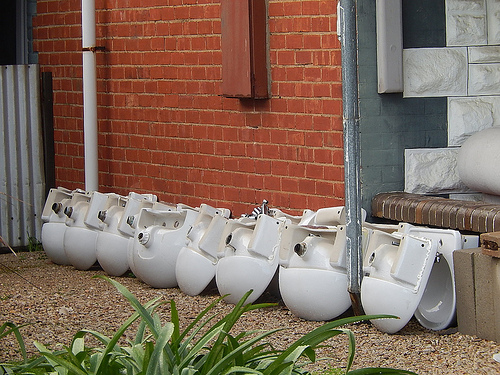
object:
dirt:
[0, 255, 138, 356]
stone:
[46, 293, 77, 318]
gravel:
[0, 271, 107, 325]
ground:
[3, 231, 498, 373]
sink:
[410, 227, 481, 332]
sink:
[213, 214, 280, 307]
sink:
[40, 187, 72, 266]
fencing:
[2, 61, 49, 248]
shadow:
[40, 69, 58, 186]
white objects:
[131, 207, 197, 289]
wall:
[354, 0, 500, 197]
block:
[400, 47, 472, 97]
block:
[447, 97, 498, 141]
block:
[402, 148, 458, 194]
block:
[466, 49, 500, 100]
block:
[442, 0, 487, 47]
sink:
[278, 224, 354, 321]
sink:
[175, 204, 229, 297]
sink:
[95, 192, 153, 277]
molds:
[403, 48, 467, 97]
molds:
[445, 0, 489, 47]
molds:
[405, 146, 465, 196]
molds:
[447, 95, 500, 148]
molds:
[466, 45, 500, 65]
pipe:
[341, 2, 360, 304]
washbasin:
[278, 224, 349, 322]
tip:
[90, 274, 101, 279]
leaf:
[93, 273, 157, 324]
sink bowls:
[63, 190, 104, 271]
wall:
[31, 1, 346, 206]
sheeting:
[0, 64, 44, 250]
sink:
[357, 228, 439, 335]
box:
[219, 0, 271, 104]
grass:
[0, 289, 419, 375]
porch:
[372, 190, 500, 232]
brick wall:
[31, 2, 347, 216]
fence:
[0, 63, 49, 250]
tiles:
[485, 0, 499, 46]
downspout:
[335, 90, 369, 314]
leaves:
[325, 313, 402, 330]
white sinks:
[412, 250, 454, 331]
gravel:
[360, 335, 499, 370]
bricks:
[55, 156, 73, 167]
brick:
[186, 119, 300, 185]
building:
[15, 0, 499, 236]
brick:
[404, 49, 477, 95]